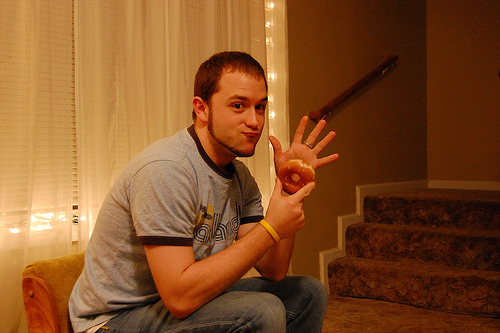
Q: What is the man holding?
A: A donut.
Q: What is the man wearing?
A: A t-shirt and jeans.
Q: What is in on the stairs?
A: Carpet.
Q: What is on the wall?
A: A hand rail.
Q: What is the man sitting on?
A: A chair.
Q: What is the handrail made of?
A: Wood.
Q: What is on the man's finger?
A: A ring.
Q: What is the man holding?
A: Donut.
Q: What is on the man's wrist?
A: Yellow band.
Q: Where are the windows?
A: Behind the man.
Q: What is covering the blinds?
A: Curtains.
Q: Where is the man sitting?
A: Green chair.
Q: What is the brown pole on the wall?
A: Stair rail.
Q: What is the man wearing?
A: Jeans and tee.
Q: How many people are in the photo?
A: One.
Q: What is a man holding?
A: A donut.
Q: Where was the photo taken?
A: In a house.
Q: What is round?
A: Donut.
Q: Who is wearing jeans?
A: A guy.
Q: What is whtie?
A: Curtains.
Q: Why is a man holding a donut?
A: To eat it.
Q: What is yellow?
A: Guy's bracelet.